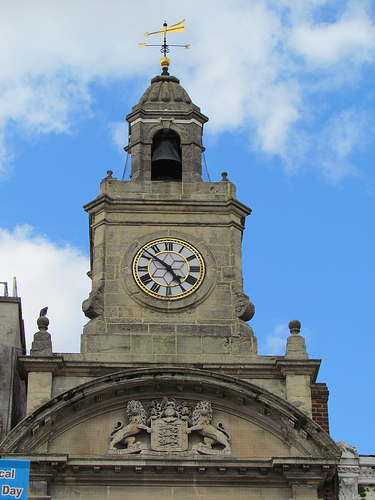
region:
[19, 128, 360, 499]
A large stone building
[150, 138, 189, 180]
An old metal bell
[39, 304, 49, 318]
A bird perched atop stone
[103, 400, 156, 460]
A stone lion statue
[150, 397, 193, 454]
A grey stone statue between two lions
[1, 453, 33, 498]
A blue sign with "cal Day" visible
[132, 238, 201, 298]
The clock says 4:53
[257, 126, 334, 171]
Wispy white clouds in the sky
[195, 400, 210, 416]
A stone lion's face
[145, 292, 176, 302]
Golden trim of the clock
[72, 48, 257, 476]
A gray stone tower on top of a building.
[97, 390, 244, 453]
Two lion carvings in the architecture.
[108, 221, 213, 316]
A clock in the center of the tower.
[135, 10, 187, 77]
A yellow windmill on top of the tower.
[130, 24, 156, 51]
Yellow Arrow heads on the windmill.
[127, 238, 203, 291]
The numbers on the clock are roman numerals.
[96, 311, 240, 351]
The tower is made of gray bricks.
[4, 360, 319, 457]
An arched structure above the lion carvings.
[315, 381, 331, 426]
An area of red brick on the side of the tower.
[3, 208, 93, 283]
A cloud in the sky behind the tower.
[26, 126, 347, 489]
An ornate stone clocktower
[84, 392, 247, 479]
Two stone lion statues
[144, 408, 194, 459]
A stone tablet in between the lions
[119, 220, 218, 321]
A large circular clock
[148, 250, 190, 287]
A six pointed golden star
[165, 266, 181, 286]
The clock's hour hand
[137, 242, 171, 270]
The clock's minute hand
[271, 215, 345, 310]
The clear blue sky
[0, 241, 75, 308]
A thick white cloud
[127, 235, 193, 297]
The clock says 5:53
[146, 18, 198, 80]
A yellow weather vane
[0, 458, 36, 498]
A blue sign with writing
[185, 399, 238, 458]
A lion statue on the building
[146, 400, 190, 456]
A stone tablet between two lion statues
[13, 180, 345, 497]
An ornate stone clock tower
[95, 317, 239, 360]
Stone bricks on the building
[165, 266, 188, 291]
Hour hand of the clock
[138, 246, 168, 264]
Minute hand of the clock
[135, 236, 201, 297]
white face of a clock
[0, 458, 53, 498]
the corner of a blue sign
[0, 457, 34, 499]
black lettering on a blue sign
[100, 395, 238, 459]
stone lions on the buildings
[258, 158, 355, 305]
blue skies over the building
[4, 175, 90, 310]
white clouds in the sky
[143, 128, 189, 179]
a black bell in the tower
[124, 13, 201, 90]
a gold wind meter on top of the building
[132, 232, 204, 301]
gold etching of the clock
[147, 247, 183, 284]
black hands of the clock